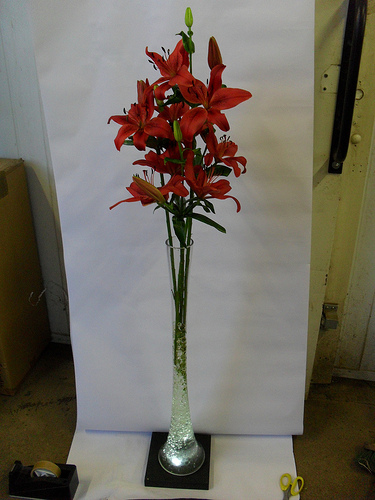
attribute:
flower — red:
[203, 135, 245, 176]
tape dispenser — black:
[5, 459, 81, 498]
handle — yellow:
[281, 472, 304, 493]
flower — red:
[139, 90, 208, 180]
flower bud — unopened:
[182, 6, 198, 27]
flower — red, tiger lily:
[111, 78, 166, 148]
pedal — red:
[167, 64, 197, 88]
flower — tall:
[140, 37, 195, 99]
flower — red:
[142, 38, 197, 101]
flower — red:
[177, 63, 252, 142]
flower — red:
[182, 149, 242, 212]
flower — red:
[202, 129, 247, 176]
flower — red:
[108, 101, 173, 150]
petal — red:
[111, 120, 138, 151]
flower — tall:
[106, 96, 177, 309]